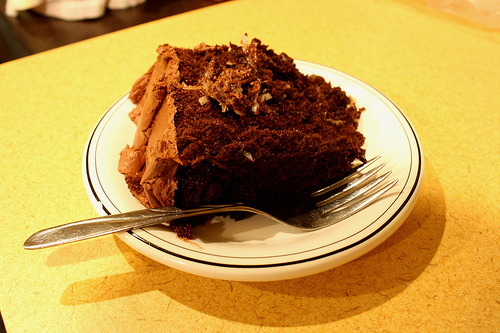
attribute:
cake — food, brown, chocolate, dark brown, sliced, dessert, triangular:
[117, 32, 369, 240]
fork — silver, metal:
[22, 155, 400, 251]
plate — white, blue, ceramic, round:
[81, 60, 425, 284]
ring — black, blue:
[85, 66, 422, 270]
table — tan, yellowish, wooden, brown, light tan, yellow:
[1, 1, 500, 332]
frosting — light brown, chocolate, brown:
[117, 43, 181, 210]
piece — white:
[198, 94, 211, 105]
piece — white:
[259, 91, 273, 103]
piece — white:
[240, 33, 249, 50]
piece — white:
[241, 149, 257, 165]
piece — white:
[219, 102, 228, 112]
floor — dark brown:
[1, 2, 234, 333]